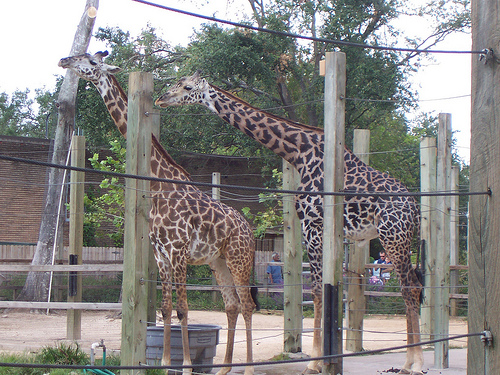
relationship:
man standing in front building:
[264, 252, 288, 290] [2, 139, 320, 307]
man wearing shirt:
[264, 252, 288, 290] [266, 267, 283, 284]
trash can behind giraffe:
[143, 326, 218, 374] [56, 50, 258, 374]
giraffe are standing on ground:
[153, 67, 432, 373] [7, 304, 496, 365]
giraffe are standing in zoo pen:
[153, 67, 432, 373] [0, 11, 495, 369]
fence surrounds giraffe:
[0, 11, 495, 369] [153, 67, 432, 373]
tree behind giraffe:
[66, 142, 154, 246] [153, 67, 432, 373]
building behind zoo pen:
[2, 139, 320, 307] [0, 11, 495, 369]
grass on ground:
[4, 349, 82, 374] [7, 304, 496, 365]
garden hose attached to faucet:
[84, 350, 116, 373] [93, 339, 106, 350]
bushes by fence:
[13, 353, 48, 374] [15, 162, 495, 374]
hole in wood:
[133, 137, 150, 169] [129, 121, 151, 219]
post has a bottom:
[322, 50, 340, 366] [321, 283, 344, 371]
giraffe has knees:
[56, 50, 258, 374] [158, 304, 190, 325]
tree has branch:
[249, 1, 473, 248] [355, 17, 469, 99]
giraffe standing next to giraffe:
[56, 50, 258, 374] [153, 67, 432, 373]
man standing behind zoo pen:
[264, 252, 288, 290] [0, 11, 495, 369]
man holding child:
[373, 254, 396, 286] [381, 257, 392, 275]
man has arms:
[373, 254, 396, 286] [382, 269, 397, 276]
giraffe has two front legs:
[56, 50, 258, 374] [157, 259, 197, 375]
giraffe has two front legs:
[153, 67, 432, 373] [307, 236, 329, 375]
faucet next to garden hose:
[93, 339, 106, 350] [84, 350, 116, 373]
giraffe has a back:
[56, 50, 258, 374] [183, 193, 244, 228]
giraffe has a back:
[153, 67, 432, 373] [358, 167, 412, 208]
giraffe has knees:
[56, 50, 258, 374] [222, 297, 254, 319]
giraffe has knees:
[153, 67, 432, 373] [399, 276, 429, 313]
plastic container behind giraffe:
[143, 326, 218, 374] [56, 50, 258, 374]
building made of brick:
[2, 139, 320, 307] [16, 202, 27, 211]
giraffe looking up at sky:
[56, 50, 258, 374] [6, 3, 496, 49]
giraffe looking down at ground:
[153, 67, 432, 373] [7, 304, 496, 365]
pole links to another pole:
[121, 69, 153, 372] [322, 50, 340, 366]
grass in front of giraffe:
[4, 349, 82, 374] [153, 67, 432, 373]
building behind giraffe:
[2, 139, 320, 307] [153, 67, 432, 373]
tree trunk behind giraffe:
[23, 1, 103, 307] [153, 67, 432, 373]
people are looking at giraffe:
[377, 251, 392, 280] [153, 67, 432, 373]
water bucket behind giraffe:
[143, 326, 218, 374] [153, 67, 432, 373]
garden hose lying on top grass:
[84, 350, 116, 373] [4, 349, 82, 374]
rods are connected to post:
[278, 40, 488, 55] [472, 17, 499, 371]